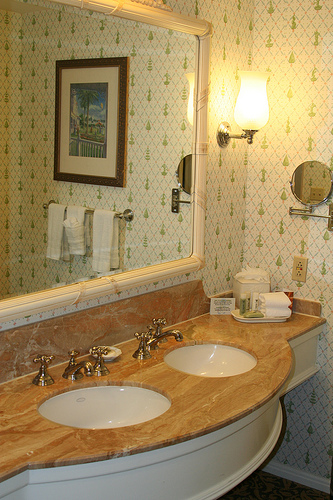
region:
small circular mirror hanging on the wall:
[286, 158, 331, 229]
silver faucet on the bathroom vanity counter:
[132, 314, 184, 361]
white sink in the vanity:
[163, 339, 259, 377]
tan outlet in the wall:
[289, 252, 310, 283]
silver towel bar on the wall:
[41, 198, 134, 222]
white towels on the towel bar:
[44, 200, 121, 272]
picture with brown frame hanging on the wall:
[52, 54, 130, 189]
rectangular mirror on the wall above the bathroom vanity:
[0, 0, 214, 326]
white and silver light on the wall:
[214, 66, 268, 146]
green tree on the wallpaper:
[286, 49, 296, 68]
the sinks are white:
[37, 330, 259, 433]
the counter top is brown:
[1, 282, 319, 481]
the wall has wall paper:
[0, 0, 329, 482]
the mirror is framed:
[1, 0, 209, 324]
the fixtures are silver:
[34, 317, 182, 385]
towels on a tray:
[265, 294, 292, 321]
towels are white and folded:
[258, 292, 291, 318]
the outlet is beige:
[292, 253, 306, 284]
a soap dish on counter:
[94, 344, 121, 358]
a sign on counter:
[208, 295, 236, 313]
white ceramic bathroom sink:
[162, 341, 259, 376]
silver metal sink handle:
[134, 331, 151, 360]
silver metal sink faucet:
[146, 326, 182, 348]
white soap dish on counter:
[91, 345, 121, 361]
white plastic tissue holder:
[233, 275, 270, 298]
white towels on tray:
[260, 291, 290, 317]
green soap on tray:
[244, 309, 261, 318]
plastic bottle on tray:
[238, 294, 247, 315]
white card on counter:
[210, 297, 234, 314]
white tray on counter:
[230, 307, 289, 322]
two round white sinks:
[35, 336, 261, 431]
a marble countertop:
[1, 280, 329, 484]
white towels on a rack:
[41, 198, 121, 274]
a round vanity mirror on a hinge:
[285, 158, 331, 223]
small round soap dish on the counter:
[88, 343, 121, 362]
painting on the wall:
[51, 52, 131, 188]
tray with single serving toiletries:
[229, 291, 291, 323]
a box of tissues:
[233, 264, 272, 309]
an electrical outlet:
[290, 252, 309, 283]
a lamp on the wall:
[214, 70, 272, 149]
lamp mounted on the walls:
[208, 57, 272, 147]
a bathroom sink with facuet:
[26, 345, 180, 433]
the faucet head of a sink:
[62, 345, 97, 385]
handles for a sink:
[27, 353, 62, 387]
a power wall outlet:
[282, 254, 314, 284]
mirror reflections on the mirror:
[0, 1, 211, 333]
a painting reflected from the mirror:
[37, 46, 142, 186]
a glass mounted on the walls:
[282, 158, 331, 217]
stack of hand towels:
[250, 290, 295, 319]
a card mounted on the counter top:
[201, 291, 243, 319]